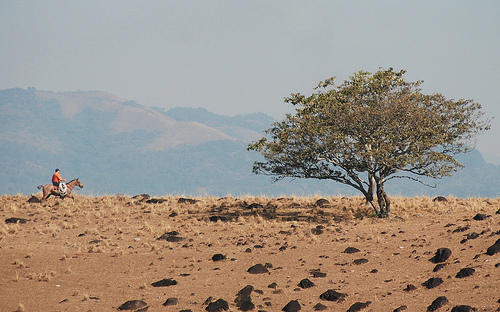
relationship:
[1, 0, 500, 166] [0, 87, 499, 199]
sky above mountain range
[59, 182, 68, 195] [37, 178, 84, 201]
rope on horse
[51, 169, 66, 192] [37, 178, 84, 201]
rider riding horse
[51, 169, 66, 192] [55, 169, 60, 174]
rider has a head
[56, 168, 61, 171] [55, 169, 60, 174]
hat on head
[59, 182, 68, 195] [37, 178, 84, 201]
rope hanging on horse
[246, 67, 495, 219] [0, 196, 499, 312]
tree growing in ground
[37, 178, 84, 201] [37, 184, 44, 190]
horse has a tail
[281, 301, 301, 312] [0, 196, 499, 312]
rock on ground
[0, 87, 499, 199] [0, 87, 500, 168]
mountain range on horizon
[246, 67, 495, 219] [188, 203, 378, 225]
tree has a shadow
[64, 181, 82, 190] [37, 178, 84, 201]
reins are on horse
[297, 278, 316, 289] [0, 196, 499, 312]
rock on ground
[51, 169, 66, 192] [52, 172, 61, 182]
rider wearing a shirt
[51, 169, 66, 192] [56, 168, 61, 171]
rider wearing a hat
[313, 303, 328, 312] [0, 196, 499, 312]
rock on ground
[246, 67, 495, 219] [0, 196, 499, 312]
tree in ground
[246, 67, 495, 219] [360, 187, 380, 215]
tree has a trunk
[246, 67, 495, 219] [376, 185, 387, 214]
tree has a trunk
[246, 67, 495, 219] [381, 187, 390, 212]
tree has a trunk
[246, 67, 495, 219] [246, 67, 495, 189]
tree has a top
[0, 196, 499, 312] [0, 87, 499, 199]
ground part of mountain range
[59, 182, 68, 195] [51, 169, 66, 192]
rope on side of rider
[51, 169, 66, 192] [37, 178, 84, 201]
rider on horse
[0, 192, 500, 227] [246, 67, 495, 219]
grassy area around tree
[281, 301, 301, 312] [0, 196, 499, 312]
rock in ground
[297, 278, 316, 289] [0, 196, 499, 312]
rock in ground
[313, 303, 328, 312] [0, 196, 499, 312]
rock in ground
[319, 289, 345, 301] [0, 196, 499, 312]
rock in ground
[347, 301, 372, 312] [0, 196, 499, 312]
rock in ground